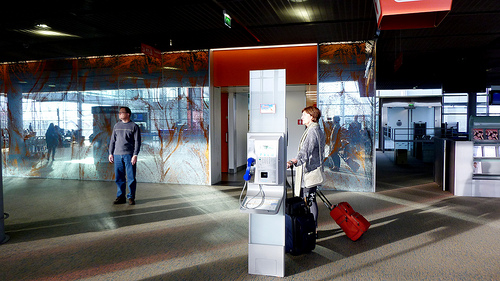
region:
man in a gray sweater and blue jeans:
[106, 104, 141, 206]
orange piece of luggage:
[313, 183, 371, 242]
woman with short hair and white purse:
[285, 102, 326, 245]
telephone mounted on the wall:
[238, 132, 287, 214]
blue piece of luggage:
[283, 195, 318, 256]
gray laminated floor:
[34, 221, 94, 259]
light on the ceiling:
[13, 18, 85, 44]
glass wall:
[3, 48, 211, 182]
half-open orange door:
[216, 83, 239, 175]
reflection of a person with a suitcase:
[327, 113, 359, 175]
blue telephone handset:
[240, 152, 262, 184]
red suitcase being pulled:
[317, 187, 381, 254]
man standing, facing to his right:
[102, 96, 174, 221]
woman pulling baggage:
[289, 101, 374, 270]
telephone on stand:
[232, 60, 299, 280]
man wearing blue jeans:
[96, 103, 159, 226]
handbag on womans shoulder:
[296, 160, 348, 190]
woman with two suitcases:
[290, 96, 397, 280]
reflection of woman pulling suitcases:
[327, 111, 352, 186]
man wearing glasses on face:
[105, 100, 150, 215]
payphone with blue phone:
[239, 120, 289, 212]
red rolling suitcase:
[321, 191, 391, 245]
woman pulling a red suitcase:
[294, 104, 389, 254]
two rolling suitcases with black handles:
[284, 158, 371, 263]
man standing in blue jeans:
[90, 90, 155, 216]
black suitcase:
[285, 181, 316, 261]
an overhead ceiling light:
[20, 13, 105, 45]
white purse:
[291, 150, 334, 195]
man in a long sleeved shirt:
[90, 90, 151, 235]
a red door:
[206, 76, 239, 188]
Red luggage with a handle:
[318, 184, 370, 240]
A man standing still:
[107, 104, 148, 205]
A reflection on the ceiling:
[272, 2, 327, 23]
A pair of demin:
[109, 153, 138, 200]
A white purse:
[301, 121, 321, 193]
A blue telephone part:
[242, 155, 257, 189]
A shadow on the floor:
[288, 191, 498, 276]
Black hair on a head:
[113, 101, 133, 119]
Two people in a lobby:
[106, 105, 338, 255]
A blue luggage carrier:
[286, 161, 314, 259]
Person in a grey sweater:
[97, 98, 154, 221]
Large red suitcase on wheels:
[311, 169, 380, 247]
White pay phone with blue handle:
[232, 126, 290, 223]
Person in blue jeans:
[100, 90, 157, 209]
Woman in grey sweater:
[279, 100, 344, 244]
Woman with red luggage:
[277, 88, 373, 255]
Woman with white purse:
[270, 86, 387, 248]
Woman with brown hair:
[270, 100, 377, 259]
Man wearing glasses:
[97, 85, 158, 216]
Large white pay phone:
[230, 119, 295, 228]